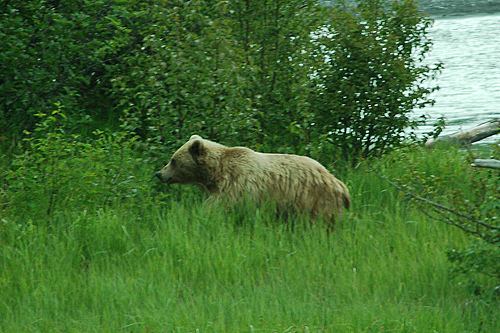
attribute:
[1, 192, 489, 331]
grass — long, green and yellow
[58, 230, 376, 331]
grass — long, green and yellow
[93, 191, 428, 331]
grass — green and yellow, long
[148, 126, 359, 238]
bear — midsize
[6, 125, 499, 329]
grass — green and yellow, long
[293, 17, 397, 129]
bushes — green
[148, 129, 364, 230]
bear — brown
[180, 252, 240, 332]
grass — long, green and yellow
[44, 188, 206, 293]
grass — green and yellow, long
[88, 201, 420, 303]
grass — long, green and yellow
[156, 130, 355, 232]
bear — brown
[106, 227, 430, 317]
grass — long, green and yellow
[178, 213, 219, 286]
grass — green and yellow, long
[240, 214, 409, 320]
grass — long, green and yellow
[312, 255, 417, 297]
grass — long, green and yellow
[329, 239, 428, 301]
grass — long, dark green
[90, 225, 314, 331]
long grass — green and yellow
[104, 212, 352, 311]
grass — tall